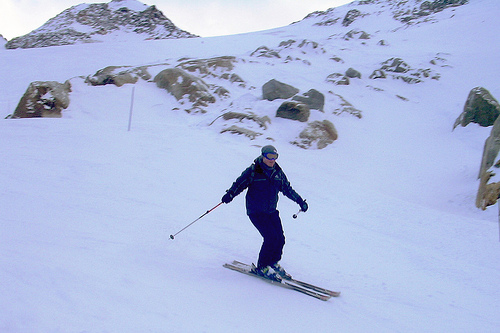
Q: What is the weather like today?
A: It is cloudy.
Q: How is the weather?
A: It is cloudy.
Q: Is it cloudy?
A: Yes, it is cloudy.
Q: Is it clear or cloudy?
A: It is cloudy.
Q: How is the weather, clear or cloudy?
A: It is cloudy.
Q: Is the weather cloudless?
A: No, it is cloudy.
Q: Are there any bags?
A: No, there are no bags.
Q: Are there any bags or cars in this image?
A: No, there are no bags or cars.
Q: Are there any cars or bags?
A: No, there are no bags or cars.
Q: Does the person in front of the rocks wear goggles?
A: Yes, the person wears goggles.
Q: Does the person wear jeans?
A: No, the person wears goggles.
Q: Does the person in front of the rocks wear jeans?
A: No, the person wears goggles.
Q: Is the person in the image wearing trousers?
A: Yes, the person is wearing trousers.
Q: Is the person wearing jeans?
A: No, the person is wearing trousers.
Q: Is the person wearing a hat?
A: Yes, the person is wearing a hat.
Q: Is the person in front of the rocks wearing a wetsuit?
A: No, the person is wearing a hat.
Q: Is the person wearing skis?
A: Yes, the person is wearing skis.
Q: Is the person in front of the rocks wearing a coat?
A: Yes, the person is wearing a coat.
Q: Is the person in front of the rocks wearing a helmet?
A: No, the person is wearing a coat.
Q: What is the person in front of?
A: The person is in front of the rocks.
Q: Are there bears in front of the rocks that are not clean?
A: No, there is a person in front of the rocks.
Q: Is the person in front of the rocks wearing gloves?
A: Yes, the person is wearing gloves.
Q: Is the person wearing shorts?
A: No, the person is wearing gloves.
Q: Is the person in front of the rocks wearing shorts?
A: No, the person is wearing gloves.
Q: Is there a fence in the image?
A: No, there are no fences.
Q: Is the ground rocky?
A: Yes, the ground is rocky.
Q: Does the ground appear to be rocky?
A: Yes, the ground is rocky.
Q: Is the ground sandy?
A: No, the ground is rocky.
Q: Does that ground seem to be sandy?
A: No, the ground is rocky.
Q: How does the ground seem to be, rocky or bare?
A: The ground is rocky.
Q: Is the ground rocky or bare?
A: The ground is rocky.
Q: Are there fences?
A: No, there are no fences.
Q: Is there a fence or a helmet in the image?
A: No, there are no fences or helmets.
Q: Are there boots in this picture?
A: Yes, there are boots.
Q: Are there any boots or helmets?
A: Yes, there are boots.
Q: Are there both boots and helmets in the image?
A: No, there are boots but no helmets.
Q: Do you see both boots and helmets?
A: No, there are boots but no helmets.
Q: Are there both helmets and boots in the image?
A: No, there are boots but no helmets.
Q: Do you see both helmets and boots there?
A: No, there are boots but no helmets.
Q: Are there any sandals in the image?
A: No, there are no sandals.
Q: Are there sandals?
A: No, there are no sandals.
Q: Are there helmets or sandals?
A: No, there are no sandals or helmets.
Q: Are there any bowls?
A: No, there are no bowls.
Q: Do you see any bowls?
A: No, there are no bowls.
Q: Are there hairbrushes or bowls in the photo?
A: No, there are no bowls or hairbrushes.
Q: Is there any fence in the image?
A: No, there are no fences.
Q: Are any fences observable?
A: No, there are no fences.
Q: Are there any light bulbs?
A: No, there are no light bulbs.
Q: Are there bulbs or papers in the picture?
A: No, there are no bulbs or papers.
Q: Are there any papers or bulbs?
A: No, there are no bulbs or papers.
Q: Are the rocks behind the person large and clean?
A: No, the rocks are large but dirty.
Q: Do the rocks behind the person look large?
A: Yes, the rocks are large.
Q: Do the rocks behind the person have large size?
A: Yes, the rocks are large.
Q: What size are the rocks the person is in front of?
A: The rocks are large.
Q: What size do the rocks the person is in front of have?
A: The rocks have large size.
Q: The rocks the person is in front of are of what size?
A: The rocks are large.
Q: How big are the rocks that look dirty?
A: The rocks are large.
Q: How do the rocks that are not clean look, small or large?
A: The rocks are large.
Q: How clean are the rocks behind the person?
A: The rocks are dirty.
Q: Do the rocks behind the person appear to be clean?
A: No, the rocks are dirty.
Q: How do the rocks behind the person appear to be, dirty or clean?
A: The rocks are dirty.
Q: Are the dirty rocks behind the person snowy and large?
A: Yes, the rocks are snowy and large.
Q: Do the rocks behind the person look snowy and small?
A: No, the rocks are snowy but large.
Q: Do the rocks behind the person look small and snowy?
A: No, the rocks are snowy but large.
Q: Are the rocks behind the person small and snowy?
A: No, the rocks are snowy but large.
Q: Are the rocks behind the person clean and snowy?
A: No, the rocks are snowy but dirty.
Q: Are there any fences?
A: No, there are no fences.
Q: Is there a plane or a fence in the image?
A: No, there are no fences or airplanes.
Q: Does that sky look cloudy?
A: Yes, the sky is cloudy.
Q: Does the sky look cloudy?
A: Yes, the sky is cloudy.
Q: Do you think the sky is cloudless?
A: No, the sky is cloudy.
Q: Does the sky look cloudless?
A: No, the sky is cloudy.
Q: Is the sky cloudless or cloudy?
A: The sky is cloudy.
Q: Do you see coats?
A: Yes, there is a coat.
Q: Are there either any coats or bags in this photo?
A: Yes, there is a coat.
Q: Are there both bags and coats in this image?
A: No, there is a coat but no bags.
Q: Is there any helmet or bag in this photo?
A: No, there are no bags or helmets.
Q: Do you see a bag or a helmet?
A: No, there are no bags or helmets.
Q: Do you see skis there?
A: Yes, there are skis.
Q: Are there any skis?
A: Yes, there are skis.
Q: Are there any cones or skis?
A: Yes, there are skis.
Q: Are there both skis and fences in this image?
A: No, there are skis but no fences.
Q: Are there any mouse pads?
A: No, there are no mouse pads.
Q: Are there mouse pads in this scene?
A: No, there are no mouse pads.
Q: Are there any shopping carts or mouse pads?
A: No, there are no mouse pads or shopping carts.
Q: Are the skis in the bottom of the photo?
A: Yes, the skis are in the bottom of the image.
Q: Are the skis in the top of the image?
A: No, the skis are in the bottom of the image.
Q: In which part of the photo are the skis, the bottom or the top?
A: The skis are in the bottom of the image.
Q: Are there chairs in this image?
A: No, there are no chairs.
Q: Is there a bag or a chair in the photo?
A: No, there are no chairs or bags.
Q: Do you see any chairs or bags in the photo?
A: No, there are no chairs or bags.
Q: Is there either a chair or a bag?
A: No, there are no chairs or bags.